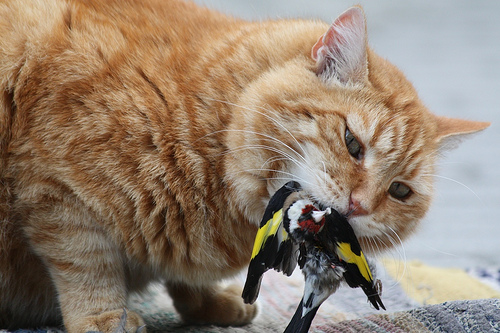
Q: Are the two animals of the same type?
A: No, they are birds and cats.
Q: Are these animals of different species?
A: Yes, they are birds and cats.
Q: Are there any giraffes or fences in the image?
A: No, there are no fences or giraffes.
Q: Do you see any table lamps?
A: No, there are no table lamps.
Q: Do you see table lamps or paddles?
A: No, there are no table lamps or paddles.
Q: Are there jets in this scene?
A: No, there are no jets.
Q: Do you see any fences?
A: No, there are no fences.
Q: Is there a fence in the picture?
A: No, there are no fences.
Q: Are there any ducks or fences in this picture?
A: No, there are no fences or ducks.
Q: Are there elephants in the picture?
A: No, there are no elephants.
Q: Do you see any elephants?
A: No, there are no elephants.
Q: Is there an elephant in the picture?
A: No, there are no elephants.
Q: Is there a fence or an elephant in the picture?
A: No, there are no elephants or fences.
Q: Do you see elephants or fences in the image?
A: No, there are no elephants or fences.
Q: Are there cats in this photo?
A: Yes, there is a cat.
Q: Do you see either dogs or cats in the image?
A: Yes, there is a cat.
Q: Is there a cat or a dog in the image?
A: Yes, there is a cat.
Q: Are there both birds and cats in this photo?
A: Yes, there are both a cat and a bird.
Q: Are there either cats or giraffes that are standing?
A: Yes, the cat is standing.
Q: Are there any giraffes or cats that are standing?
A: Yes, the cat is standing.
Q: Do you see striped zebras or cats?
A: Yes, there is a striped cat.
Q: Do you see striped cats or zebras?
A: Yes, there is a striped cat.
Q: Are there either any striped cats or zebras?
A: Yes, there is a striped cat.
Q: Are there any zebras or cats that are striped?
A: Yes, the cat is striped.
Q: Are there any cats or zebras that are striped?
A: Yes, the cat is striped.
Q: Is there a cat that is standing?
A: Yes, there is a cat that is standing.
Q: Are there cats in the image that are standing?
A: Yes, there is a cat that is standing.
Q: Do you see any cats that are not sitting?
A: Yes, there is a cat that is standing .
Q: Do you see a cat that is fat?
A: Yes, there is a fat cat.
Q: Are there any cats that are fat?
A: Yes, there is a cat that is fat.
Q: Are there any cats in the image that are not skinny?
A: Yes, there is a fat cat.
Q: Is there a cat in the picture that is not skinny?
A: Yes, there is a fat cat.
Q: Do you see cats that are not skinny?
A: Yes, there is a fat cat.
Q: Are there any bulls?
A: No, there are no bulls.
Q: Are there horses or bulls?
A: No, there are no bulls or horses.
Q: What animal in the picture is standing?
A: The animal is a cat.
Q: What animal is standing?
A: The animal is a cat.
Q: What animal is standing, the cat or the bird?
A: The cat is standing.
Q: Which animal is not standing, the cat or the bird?
A: The bird is not standing.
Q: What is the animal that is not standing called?
A: The animal is a bird.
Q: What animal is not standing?
A: The animal is a bird.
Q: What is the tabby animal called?
A: The animal is a cat.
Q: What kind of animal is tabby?
A: The animal is a cat.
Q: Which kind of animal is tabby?
A: The animal is a cat.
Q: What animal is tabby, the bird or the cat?
A: The cat is tabby.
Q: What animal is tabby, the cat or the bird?
A: The cat is tabby.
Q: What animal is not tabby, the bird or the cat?
A: The bird is not tabby.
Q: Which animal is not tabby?
A: The animal is a bird.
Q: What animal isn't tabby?
A: The animal is a bird.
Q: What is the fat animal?
A: The animal is a cat.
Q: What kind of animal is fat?
A: The animal is a cat.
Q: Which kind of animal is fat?
A: The animal is a cat.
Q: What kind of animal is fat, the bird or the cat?
A: The cat is fat.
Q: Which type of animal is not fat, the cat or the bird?
A: The bird is not fat.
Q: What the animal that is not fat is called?
A: The animal is a bird.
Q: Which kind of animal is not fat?
A: The animal is a bird.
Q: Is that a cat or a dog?
A: That is a cat.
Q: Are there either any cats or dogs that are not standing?
A: No, there is a cat but it is standing.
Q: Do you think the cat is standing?
A: Yes, the cat is standing.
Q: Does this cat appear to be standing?
A: Yes, the cat is standing.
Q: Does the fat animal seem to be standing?
A: Yes, the cat is standing.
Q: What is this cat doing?
A: The cat is standing.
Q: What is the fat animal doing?
A: The cat is standing.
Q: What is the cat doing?
A: The cat is standing.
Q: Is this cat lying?
A: No, the cat is standing.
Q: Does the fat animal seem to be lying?
A: No, the cat is standing.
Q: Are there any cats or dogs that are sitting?
A: No, there is a cat but it is standing.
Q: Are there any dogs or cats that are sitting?
A: No, there is a cat but it is standing.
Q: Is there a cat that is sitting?
A: No, there is a cat but it is standing.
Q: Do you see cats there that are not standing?
A: No, there is a cat but it is standing.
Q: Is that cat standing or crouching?
A: The cat is standing.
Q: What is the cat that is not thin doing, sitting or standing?
A: The cat is standing.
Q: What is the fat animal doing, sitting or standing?
A: The cat is standing.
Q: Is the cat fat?
A: Yes, the cat is fat.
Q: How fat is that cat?
A: The cat is fat.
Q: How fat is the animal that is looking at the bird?
A: The cat is fat.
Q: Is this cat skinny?
A: No, the cat is fat.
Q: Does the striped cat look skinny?
A: No, the cat is fat.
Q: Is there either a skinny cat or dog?
A: No, there is a cat but it is fat.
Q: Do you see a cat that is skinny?
A: No, there is a cat but it is fat.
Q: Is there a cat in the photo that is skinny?
A: No, there is a cat but it is fat.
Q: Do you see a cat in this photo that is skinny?
A: No, there is a cat but it is fat.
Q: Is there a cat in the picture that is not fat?
A: No, there is a cat but it is fat.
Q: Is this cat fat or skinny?
A: The cat is fat.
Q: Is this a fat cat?
A: Yes, this is a fat cat.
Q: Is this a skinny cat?
A: No, this is a fat cat.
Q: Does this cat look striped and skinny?
A: No, the cat is striped but fat.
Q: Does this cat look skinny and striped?
A: No, the cat is striped but fat.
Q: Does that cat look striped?
A: Yes, the cat is striped.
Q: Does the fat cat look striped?
A: Yes, the cat is striped.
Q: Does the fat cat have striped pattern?
A: Yes, the cat is striped.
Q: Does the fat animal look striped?
A: Yes, the cat is striped.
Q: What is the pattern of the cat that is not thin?
A: The cat is striped.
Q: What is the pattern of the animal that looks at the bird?
A: The cat is striped.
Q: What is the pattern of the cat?
A: The cat is striped.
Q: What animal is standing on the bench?
A: The cat is standing on the bench.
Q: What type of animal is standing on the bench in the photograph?
A: The animal is a cat.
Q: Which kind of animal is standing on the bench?
A: The animal is a cat.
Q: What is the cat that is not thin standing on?
A: The cat is standing on the bench.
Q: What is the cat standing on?
A: The cat is standing on the bench.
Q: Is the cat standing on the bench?
A: Yes, the cat is standing on the bench.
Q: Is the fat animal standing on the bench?
A: Yes, the cat is standing on the bench.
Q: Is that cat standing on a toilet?
A: No, the cat is standing on the bench.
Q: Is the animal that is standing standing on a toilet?
A: No, the cat is standing on the bench.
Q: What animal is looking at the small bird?
A: The cat is looking at the bird.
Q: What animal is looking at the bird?
A: The cat is looking at the bird.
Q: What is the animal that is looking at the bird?
A: The animal is a cat.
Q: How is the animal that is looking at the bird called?
A: The animal is a cat.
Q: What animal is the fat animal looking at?
A: The cat is looking at the bird.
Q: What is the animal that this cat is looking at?
A: The animal is a bird.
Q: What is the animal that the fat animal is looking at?
A: The animal is a bird.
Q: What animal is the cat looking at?
A: The cat is looking at the bird.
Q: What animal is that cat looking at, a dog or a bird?
A: The cat is looking at a bird.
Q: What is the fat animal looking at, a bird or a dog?
A: The cat is looking at a bird.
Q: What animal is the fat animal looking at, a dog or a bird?
A: The cat is looking at a bird.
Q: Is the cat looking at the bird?
A: Yes, the cat is looking at the bird.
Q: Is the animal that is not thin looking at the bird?
A: Yes, the cat is looking at the bird.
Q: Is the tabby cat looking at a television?
A: No, the cat is looking at the bird.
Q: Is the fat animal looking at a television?
A: No, the cat is looking at the bird.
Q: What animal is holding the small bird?
A: The cat is holding the bird.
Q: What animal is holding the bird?
A: The cat is holding the bird.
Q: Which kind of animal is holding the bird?
A: The animal is a cat.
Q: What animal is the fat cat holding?
A: The cat is holding the bird.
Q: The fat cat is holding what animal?
A: The cat is holding the bird.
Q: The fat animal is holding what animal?
A: The cat is holding the bird.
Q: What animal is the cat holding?
A: The cat is holding the bird.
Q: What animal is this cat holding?
A: The cat is holding the bird.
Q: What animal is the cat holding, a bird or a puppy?
A: The cat is holding a bird.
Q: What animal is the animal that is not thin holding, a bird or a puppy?
A: The cat is holding a bird.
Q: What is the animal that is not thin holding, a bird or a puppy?
A: The cat is holding a bird.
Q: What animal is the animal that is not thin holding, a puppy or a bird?
A: The cat is holding a bird.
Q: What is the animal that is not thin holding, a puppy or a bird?
A: The cat is holding a bird.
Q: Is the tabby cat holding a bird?
A: Yes, the cat is holding a bird.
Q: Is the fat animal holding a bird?
A: Yes, the cat is holding a bird.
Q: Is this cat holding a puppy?
A: No, the cat is holding a bird.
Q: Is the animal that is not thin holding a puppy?
A: No, the cat is holding a bird.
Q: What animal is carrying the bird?
A: The cat is carrying the bird.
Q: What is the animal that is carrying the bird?
A: The animal is a cat.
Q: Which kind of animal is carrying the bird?
A: The animal is a cat.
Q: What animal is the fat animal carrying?
A: The cat is carrying a bird.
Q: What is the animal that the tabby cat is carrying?
A: The animal is a bird.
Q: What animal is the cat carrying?
A: The cat is carrying a bird.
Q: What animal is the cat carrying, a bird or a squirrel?
A: The cat is carrying a bird.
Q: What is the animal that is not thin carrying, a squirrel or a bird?
A: The cat is carrying a bird.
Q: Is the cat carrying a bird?
A: Yes, the cat is carrying a bird.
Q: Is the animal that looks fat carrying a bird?
A: Yes, the cat is carrying a bird.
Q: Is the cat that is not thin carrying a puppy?
A: No, the cat is carrying a bird.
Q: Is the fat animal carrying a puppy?
A: No, the cat is carrying a bird.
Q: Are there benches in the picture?
A: Yes, there is a bench.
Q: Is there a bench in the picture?
A: Yes, there is a bench.